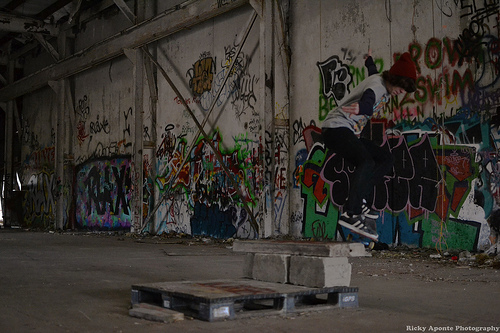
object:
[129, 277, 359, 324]
pallet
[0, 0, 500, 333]
warehouse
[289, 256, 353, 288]
cinder block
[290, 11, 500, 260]
graffiti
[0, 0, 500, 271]
wall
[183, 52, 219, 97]
graffiti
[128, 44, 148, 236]
beam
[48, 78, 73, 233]
beam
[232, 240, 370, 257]
slab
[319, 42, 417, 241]
skateboarder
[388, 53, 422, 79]
cap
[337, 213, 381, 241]
shoes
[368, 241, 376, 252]
wheel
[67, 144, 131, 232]
graffiti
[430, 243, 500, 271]
trash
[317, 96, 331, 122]
letters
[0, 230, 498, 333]
ground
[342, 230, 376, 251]
skateboard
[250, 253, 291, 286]
cinder block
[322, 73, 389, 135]
shirt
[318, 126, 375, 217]
clothes